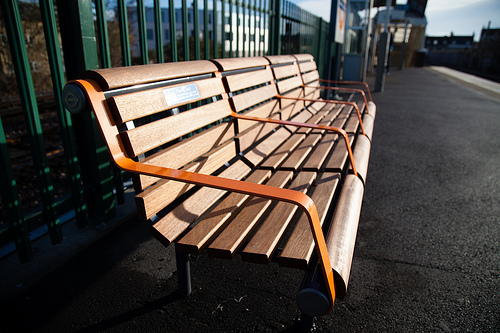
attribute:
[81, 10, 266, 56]
fence — metal, green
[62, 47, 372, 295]
fence — green, metal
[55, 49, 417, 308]
bench — sunlit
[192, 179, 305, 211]
arm rest — metal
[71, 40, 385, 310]
bench — green, bus stop, brown, wooden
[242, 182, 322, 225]
arm rest — metal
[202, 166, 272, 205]
arm rest — metal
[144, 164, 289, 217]
arm rest — metal, orange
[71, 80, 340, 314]
arm rest — orange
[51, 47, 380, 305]
bench — bus station, wooden, large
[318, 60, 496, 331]
sidewalk — gravel-filled, black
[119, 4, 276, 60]
building — large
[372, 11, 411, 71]
opening — covered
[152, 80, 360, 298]
chair arms — five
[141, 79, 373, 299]
arms — orange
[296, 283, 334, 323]
end cap — silver, round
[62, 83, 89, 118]
end cap — silver, round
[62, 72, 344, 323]
arm — orange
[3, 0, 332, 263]
fencing slats — vertical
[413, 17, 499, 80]
buildings — blurry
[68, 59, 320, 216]
back — wooden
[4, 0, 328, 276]
fence — green, wrought iron, hunter green, tall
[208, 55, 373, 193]
bench — second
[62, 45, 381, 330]
bench — wooden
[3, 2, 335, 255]
gate — green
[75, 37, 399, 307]
benches — four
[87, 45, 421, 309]
benches — four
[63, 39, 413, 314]
benches — street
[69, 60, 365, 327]
bench — first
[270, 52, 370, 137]
bench — third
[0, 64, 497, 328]
walk area — concrete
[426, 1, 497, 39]
sky — cloudy, evening, sunless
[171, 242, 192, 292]
pole — gray